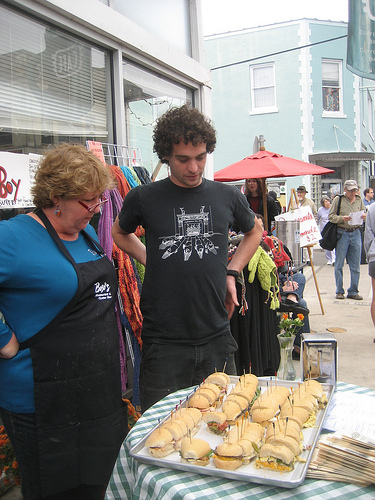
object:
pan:
[130, 366, 335, 491]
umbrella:
[211, 143, 334, 188]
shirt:
[113, 174, 259, 346]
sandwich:
[209, 436, 246, 472]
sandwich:
[174, 431, 214, 472]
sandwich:
[204, 406, 233, 439]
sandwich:
[181, 385, 212, 411]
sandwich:
[297, 372, 328, 395]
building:
[182, 0, 375, 270]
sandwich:
[277, 397, 313, 425]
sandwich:
[145, 421, 180, 461]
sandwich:
[251, 442, 301, 472]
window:
[321, 58, 342, 116]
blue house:
[186, 12, 372, 272]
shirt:
[326, 193, 366, 231]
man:
[326, 178, 366, 303]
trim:
[294, 25, 315, 158]